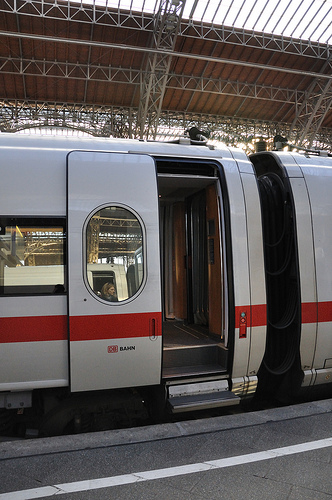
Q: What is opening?
A: The train door.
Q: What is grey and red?
A: The train.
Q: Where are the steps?
A: On the train.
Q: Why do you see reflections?
A: The train windows.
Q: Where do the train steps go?
A: Inside the train.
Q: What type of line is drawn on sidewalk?
A: A solid white line.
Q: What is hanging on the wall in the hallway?
A: Two signs.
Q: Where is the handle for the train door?
A: On the red stripe.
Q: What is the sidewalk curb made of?
A: Concrete.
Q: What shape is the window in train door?
A: Oblong.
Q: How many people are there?
A: One.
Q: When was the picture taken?
A: Daytime.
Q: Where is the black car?
A: No car.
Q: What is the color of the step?
A: Silver.